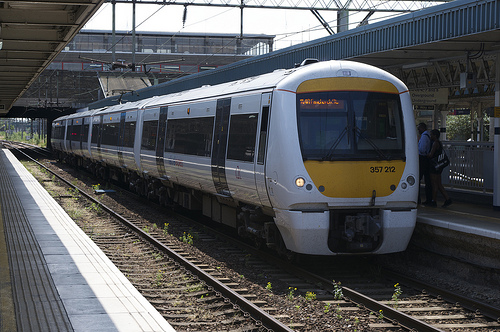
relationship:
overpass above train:
[67, 35, 279, 60] [50, 57, 417, 252]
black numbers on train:
[369, 165, 397, 173] [138, 57, 419, 261]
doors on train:
[202, 94, 241, 186] [84, 38, 404, 242]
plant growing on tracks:
[374, 309, 386, 322] [314, 254, 499, 327]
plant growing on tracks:
[374, 309, 386, 322] [314, 266, 499, 331]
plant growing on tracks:
[361, 300, 390, 328] [314, 254, 499, 327]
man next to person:
[422, 111, 457, 223] [424, 131, 454, 203]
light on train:
[295, 176, 304, 186] [50, 57, 417, 252]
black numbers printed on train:
[369, 161, 397, 173] [50, 57, 417, 252]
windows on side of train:
[99, 122, 120, 146] [50, 57, 417, 252]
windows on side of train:
[88, 110, 140, 147] [50, 57, 417, 252]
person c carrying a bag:
[425, 129, 453, 213] [425, 157, 451, 174]